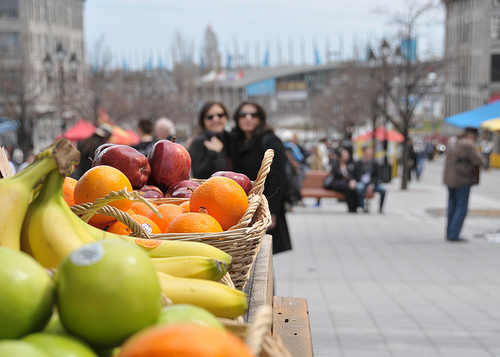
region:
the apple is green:
[28, 181, 140, 291]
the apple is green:
[41, 223, 156, 338]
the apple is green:
[97, 232, 231, 355]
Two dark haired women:
[191, 90, 274, 141]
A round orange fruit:
[189, 165, 247, 228]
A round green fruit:
[55, 238, 162, 329]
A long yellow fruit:
[44, 201, 214, 289]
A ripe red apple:
[153, 138, 188, 190]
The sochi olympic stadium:
[243, 43, 437, 120]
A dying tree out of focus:
[366, 25, 425, 190]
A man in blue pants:
[436, 126, 489, 253]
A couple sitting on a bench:
[321, 143, 390, 214]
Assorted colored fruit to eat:
[24, 131, 259, 306]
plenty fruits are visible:
[71, 168, 271, 296]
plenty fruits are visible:
[10, 87, 202, 242]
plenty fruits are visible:
[111, 201, 162, 246]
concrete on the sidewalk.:
[379, 291, 441, 336]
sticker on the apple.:
[65, 252, 137, 269]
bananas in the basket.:
[41, 199, 66, 241]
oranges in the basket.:
[189, 183, 227, 227]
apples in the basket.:
[135, 141, 177, 173]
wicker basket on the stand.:
[237, 229, 259, 268]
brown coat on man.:
[451, 157, 471, 179]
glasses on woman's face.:
[203, 108, 218, 120]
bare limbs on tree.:
[389, 51, 419, 96]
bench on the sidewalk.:
[308, 177, 323, 196]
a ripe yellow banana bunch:
[8, 139, 250, 319]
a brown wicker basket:
[70, 146, 281, 285]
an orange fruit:
[185, 177, 245, 229]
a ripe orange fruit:
[165, 206, 224, 234]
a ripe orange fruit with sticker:
[103, 207, 158, 239]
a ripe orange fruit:
[75, 162, 133, 224]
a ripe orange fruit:
[148, 201, 183, 228]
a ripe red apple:
[148, 136, 192, 191]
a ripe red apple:
[95, 137, 147, 185]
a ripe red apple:
[211, 167, 253, 190]